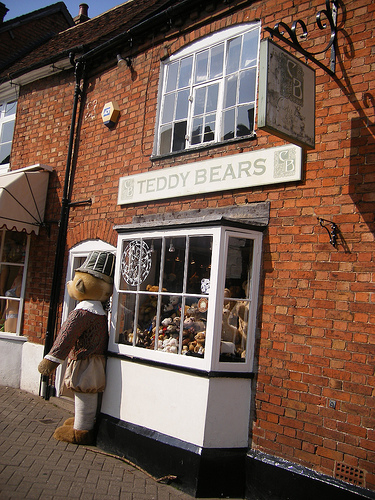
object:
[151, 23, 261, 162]
window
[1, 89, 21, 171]
window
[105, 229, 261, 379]
window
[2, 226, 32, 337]
window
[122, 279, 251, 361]
animals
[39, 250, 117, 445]
bear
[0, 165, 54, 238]
awning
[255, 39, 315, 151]
sign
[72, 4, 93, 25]
chimney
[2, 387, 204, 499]
sidewalk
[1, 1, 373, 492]
wall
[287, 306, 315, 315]
brick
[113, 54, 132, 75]
lamp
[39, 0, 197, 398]
pipes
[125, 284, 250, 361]
bears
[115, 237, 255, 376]
display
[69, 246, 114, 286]
hat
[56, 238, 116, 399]
door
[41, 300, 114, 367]
sweater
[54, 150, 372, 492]
shop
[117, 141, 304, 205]
sign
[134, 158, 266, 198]
teddy bears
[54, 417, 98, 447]
feet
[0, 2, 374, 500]
building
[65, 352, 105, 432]
leg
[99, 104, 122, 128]
sign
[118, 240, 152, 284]
design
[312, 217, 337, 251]
fixture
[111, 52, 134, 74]
light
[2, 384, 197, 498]
ground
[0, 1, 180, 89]
roof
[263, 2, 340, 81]
scrollwork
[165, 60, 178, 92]
window pane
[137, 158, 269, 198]
word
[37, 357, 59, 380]
paw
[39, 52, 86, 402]
pipe